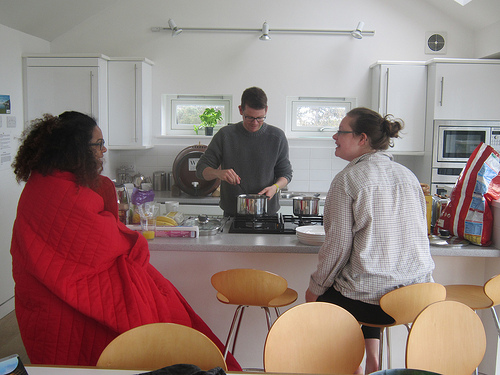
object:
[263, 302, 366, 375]
stool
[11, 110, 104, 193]
curly hair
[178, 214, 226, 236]
pot lid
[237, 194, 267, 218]
pot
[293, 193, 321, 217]
pot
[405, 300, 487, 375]
stool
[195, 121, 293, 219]
shirt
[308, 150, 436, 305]
plaid shirt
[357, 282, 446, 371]
stool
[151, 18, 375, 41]
lights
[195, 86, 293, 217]
man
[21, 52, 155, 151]
cabinet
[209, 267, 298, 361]
stool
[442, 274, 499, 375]
stool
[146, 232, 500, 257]
counter top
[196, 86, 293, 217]
picture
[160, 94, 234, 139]
window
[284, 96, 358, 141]
window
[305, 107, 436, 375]
person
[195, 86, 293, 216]
person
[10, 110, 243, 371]
person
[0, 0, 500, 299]
kitchen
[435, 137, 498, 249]
snack bag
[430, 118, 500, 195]
microwave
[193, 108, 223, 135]
plant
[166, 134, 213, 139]
windowsill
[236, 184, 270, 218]
stiring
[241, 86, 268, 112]
hair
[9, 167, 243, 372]
blanket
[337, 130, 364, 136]
glasses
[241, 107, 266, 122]
glasses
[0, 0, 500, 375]
home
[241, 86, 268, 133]
head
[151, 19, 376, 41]
track